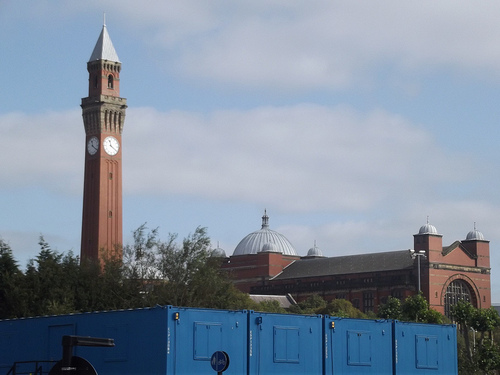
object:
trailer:
[0, 305, 250, 375]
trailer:
[247, 311, 323, 375]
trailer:
[323, 314, 399, 375]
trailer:
[392, 321, 459, 375]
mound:
[466, 221, 485, 240]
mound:
[418, 215, 437, 234]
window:
[104, 67, 113, 93]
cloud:
[0, 0, 500, 272]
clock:
[87, 136, 99, 155]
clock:
[103, 135, 120, 156]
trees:
[287, 294, 365, 317]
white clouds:
[1, 0, 498, 302]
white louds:
[165, 102, 498, 210]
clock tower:
[80, 10, 128, 288]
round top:
[230, 203, 297, 255]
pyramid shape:
[88, 21, 119, 61]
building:
[180, 201, 495, 324]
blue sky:
[0, 0, 499, 304]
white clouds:
[185, 0, 498, 100]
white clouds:
[158, 97, 217, 189]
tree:
[308, 292, 365, 318]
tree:
[381, 287, 451, 325]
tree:
[100, 221, 229, 307]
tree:
[2, 238, 115, 317]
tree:
[443, 289, 497, 372]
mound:
[228, 209, 297, 256]